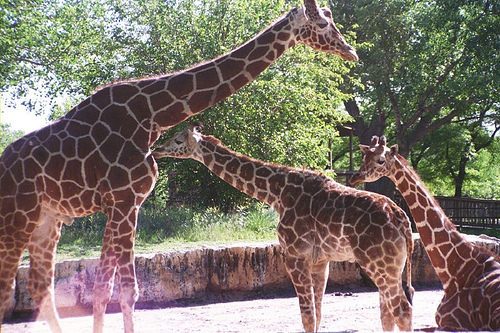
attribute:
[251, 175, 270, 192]
spot — brown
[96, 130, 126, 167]
patches — brown, white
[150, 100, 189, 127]
patches — white, brown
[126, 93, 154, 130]
patches — white, brown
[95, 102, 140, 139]
patches — white, brown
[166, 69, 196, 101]
patches — white, brown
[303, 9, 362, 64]
face — giraffe's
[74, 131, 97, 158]
spot — brown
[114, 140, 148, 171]
spot — brown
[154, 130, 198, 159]
face — giraffe's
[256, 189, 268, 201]
spot — brown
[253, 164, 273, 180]
spot — brown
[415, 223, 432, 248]
spot — brown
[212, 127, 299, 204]
neck — long